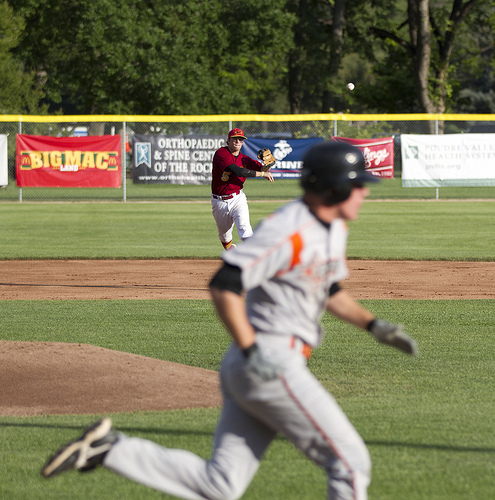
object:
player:
[47, 138, 422, 499]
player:
[210, 127, 275, 250]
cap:
[228, 127, 248, 141]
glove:
[255, 147, 276, 167]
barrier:
[3, 112, 495, 192]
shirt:
[212, 148, 262, 196]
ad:
[17, 132, 123, 188]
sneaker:
[40, 419, 120, 475]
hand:
[264, 171, 273, 181]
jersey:
[224, 205, 351, 343]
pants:
[108, 331, 372, 495]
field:
[0, 201, 488, 499]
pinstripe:
[275, 368, 359, 495]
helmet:
[298, 143, 384, 189]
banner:
[399, 132, 495, 186]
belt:
[215, 188, 240, 202]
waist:
[260, 169, 266, 177]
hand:
[259, 148, 272, 166]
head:
[297, 141, 375, 220]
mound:
[5, 341, 224, 416]